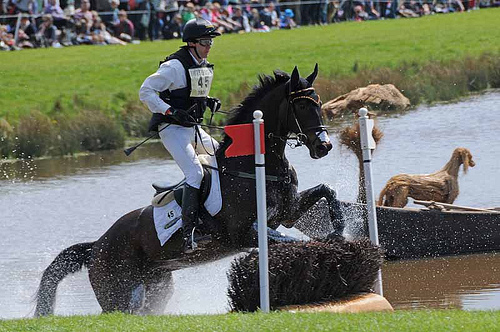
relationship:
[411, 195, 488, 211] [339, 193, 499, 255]
paddle in boat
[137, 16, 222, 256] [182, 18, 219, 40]
man wearing hat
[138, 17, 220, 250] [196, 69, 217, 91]
jockey wearing number sign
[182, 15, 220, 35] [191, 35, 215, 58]
hat on head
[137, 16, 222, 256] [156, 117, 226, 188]
man wearing pants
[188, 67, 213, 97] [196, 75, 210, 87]
bib has number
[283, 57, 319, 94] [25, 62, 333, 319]
pointed ears on horse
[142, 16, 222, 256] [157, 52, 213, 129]
man wearing vest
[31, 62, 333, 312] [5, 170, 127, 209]
horse jumping from water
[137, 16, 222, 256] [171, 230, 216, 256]
man wearing boot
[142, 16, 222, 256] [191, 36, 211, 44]
man wearing goggles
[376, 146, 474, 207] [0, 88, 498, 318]
dog standing in water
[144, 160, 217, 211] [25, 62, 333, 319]
saddle on horse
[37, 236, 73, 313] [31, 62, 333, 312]
tail on horse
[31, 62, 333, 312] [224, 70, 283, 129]
horse has hair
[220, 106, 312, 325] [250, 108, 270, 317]
flag on pole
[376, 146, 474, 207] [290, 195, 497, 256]
dog standing in boat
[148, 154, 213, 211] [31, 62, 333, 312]
saddle on horse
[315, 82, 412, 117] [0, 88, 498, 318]
rock beside water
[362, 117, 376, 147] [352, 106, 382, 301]
flag on pole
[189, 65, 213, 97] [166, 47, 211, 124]
45 on chest